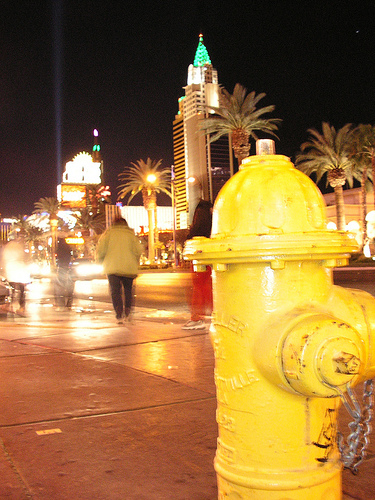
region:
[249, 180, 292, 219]
top of yellow fire hydrant.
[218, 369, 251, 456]
writing on yellow fire hydrant.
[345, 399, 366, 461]
chain connected to fire hydrant.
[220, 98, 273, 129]
leaves on palm tree.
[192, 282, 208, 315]
red pants worn by person.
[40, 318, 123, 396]
sidewalk with light reflection.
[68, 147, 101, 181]
large neon sign.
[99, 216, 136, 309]
person walking on sidewalk.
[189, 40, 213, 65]
top of tall building.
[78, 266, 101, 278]
headlights from oncoming vehicles.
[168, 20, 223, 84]
Blue roof of a building.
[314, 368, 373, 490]
Silver chain hanging.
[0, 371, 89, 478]
Paper on the cement.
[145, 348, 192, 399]
Garbage on the ground.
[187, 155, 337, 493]
Yellow fire hydrant on side walk.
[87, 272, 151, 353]
Pair of Blue jeans.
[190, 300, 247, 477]
Letters on a hydrant.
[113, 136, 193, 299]
Palm tree with branches.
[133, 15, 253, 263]
Tall building with blue roof.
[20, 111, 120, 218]
The lights of Las Vegas.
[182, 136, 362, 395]
a yellow fire hydrant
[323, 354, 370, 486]
a silver chain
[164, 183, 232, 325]
a person wearing red pants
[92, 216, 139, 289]
a person wearing a tan jacket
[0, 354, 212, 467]
a cement sidewalk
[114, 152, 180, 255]
a tall palm tree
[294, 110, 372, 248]
two palm trees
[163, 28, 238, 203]
a tall building with windows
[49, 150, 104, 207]
a neon sign on top of a building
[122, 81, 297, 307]
a palm tree beside a road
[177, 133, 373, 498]
Fire hydrant is yellow.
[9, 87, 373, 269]
There are palm trees lining the street.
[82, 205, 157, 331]
The woman is walking on sidewalk.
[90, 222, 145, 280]
Woman is wearing a jacket.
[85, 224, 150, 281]
The jacket is tan.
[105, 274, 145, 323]
Woman is wearing pants.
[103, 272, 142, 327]
Woman's pants are black.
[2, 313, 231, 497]
The sidewalk is dry.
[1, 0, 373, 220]
The picture was taken at nighttime.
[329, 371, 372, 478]
There's a chain on fire hydrant.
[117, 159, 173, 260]
tall light brown and green palmtree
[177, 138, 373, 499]
yellow metal fire hydrant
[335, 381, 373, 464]
shiny silver chain link chain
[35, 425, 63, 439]
one hundred dollar bill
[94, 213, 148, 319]
average sized woman walking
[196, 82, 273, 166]
very tall palm tree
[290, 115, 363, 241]
very tall palm tree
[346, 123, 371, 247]
very tall palm tree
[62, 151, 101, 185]
very bright set of lights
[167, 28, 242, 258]
very tall lit up building